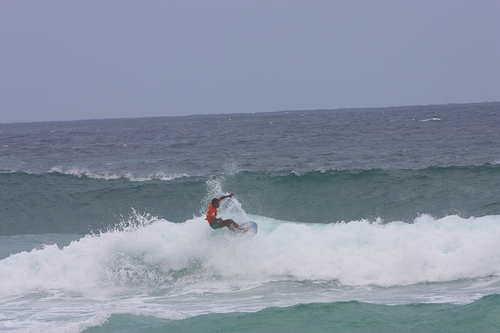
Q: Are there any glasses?
A: No, there are no glasses.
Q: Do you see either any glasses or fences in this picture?
A: No, there are no glasses or fences.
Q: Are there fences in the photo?
A: No, there are no fences.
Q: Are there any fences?
A: No, there are no fences.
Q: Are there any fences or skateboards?
A: No, there are no fences or skateboards.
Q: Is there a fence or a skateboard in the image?
A: No, there are no fences or skateboards.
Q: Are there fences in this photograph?
A: No, there are no fences.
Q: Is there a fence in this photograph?
A: No, there are no fences.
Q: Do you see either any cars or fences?
A: No, there are no fences or cars.